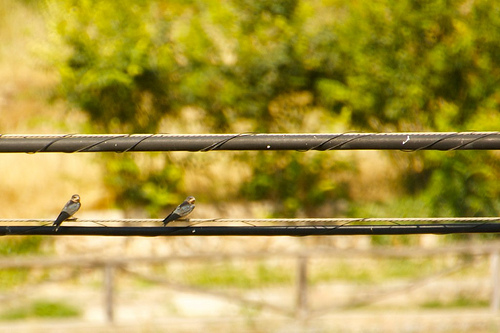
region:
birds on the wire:
[44, 180, 220, 230]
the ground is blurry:
[63, 253, 347, 320]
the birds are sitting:
[47, 183, 183, 240]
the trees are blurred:
[68, 18, 468, 107]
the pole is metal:
[4, 123, 281, 144]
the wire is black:
[240, 221, 335, 238]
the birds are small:
[52, 197, 196, 225]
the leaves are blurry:
[407, 166, 487, 209]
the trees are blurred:
[31, 25, 173, 108]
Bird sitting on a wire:
[53, 190, 210, 236]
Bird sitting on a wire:
[51, 190, 92, 229]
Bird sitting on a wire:
[168, 188, 205, 235]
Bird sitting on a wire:
[40, 184, 220, 248]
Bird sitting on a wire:
[160, 191, 214, 228]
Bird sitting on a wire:
[43, 195, 104, 224]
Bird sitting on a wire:
[154, 187, 197, 232]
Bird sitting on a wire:
[41, 183, 93, 225]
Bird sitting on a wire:
[154, 190, 220, 234]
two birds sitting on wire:
[53, 187, 211, 242]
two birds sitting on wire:
[45, 175, 200, 236]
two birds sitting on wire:
[47, 170, 197, 245]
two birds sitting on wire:
[45, 180, 205, 235]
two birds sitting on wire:
[56, 172, 211, 239]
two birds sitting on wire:
[48, 185, 205, 242]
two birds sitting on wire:
[38, 170, 199, 246]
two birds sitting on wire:
[48, 177, 203, 252]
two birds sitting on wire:
[53, 186, 201, 246]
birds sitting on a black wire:
[1, 101, 492, 247]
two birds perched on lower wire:
[40, 176, 202, 233]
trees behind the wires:
[48, 6, 491, 211]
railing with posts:
[1, 245, 493, 330]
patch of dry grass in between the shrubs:
[0, 153, 401, 216]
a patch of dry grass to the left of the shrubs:
[6, 15, 98, 205]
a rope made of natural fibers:
[1, 205, 497, 220]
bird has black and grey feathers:
[155, 191, 195, 221]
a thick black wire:
[13, 124, 498, 145]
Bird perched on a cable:
[48, 192, 84, 232]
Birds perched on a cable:
[47, 192, 199, 229]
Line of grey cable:
[0, 214, 499, 223]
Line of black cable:
[1, 223, 498, 237]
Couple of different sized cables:
[1, 214, 498, 236]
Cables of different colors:
[0, 214, 499, 236]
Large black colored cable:
[1, 129, 499, 153]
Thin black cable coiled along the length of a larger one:
[1, 129, 499, 154]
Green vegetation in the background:
[32, 0, 499, 252]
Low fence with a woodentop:
[1, 242, 499, 332]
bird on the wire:
[52, 189, 84, 230]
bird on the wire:
[165, 194, 195, 221]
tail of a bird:
[52, 217, 65, 229]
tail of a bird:
[161, 214, 178, 224]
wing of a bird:
[179, 203, 193, 214]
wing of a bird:
[65, 202, 80, 215]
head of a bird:
[187, 196, 195, 204]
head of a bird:
[71, 193, 78, 202]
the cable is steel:
[0, 133, 498, 149]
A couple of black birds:
[48, 185, 203, 240]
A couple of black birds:
[50, 187, 200, 233]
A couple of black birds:
[44, 188, 201, 231]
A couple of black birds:
[51, 192, 201, 232]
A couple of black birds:
[46, 190, 201, 237]